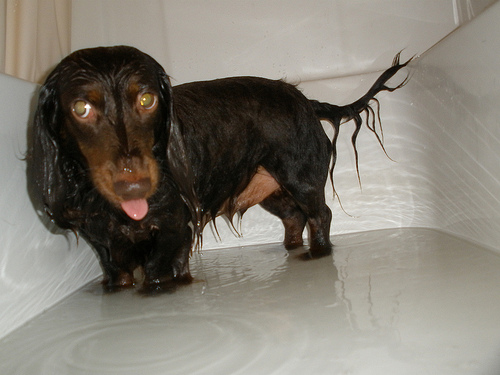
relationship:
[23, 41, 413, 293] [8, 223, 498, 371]
dog in water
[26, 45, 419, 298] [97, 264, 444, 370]
dog standing in water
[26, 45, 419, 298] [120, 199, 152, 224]
dog sticking out tongue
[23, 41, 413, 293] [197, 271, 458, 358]
dog in water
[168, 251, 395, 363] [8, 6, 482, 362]
water in tub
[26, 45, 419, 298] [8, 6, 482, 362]
dog in tub